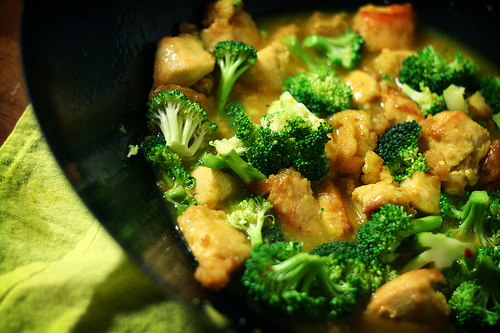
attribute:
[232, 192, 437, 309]
vegetable — green, fresh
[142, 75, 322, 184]
vegetable — green, fresh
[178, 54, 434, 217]
vegetable — fresh, green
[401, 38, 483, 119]
green vegetable — fresh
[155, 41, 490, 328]
food — delicious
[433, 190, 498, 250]
vegetable — fresh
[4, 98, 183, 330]
towel — green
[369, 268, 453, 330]
meat — brown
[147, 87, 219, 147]
vegetable — green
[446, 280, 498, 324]
vegitable — green, fresh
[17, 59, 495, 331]
vegetable — green, fresh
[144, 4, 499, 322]
food — green, brown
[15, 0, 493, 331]
plate — black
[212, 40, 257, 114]
vegetable — fresh, green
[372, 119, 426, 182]
vegetable — green, fresh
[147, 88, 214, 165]
vegetable — green, fresh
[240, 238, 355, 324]
vegetable — green, fresh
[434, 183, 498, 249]
vegetable — green, fresh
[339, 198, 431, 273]
vegetable — green, fresh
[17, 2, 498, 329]
bowl — black